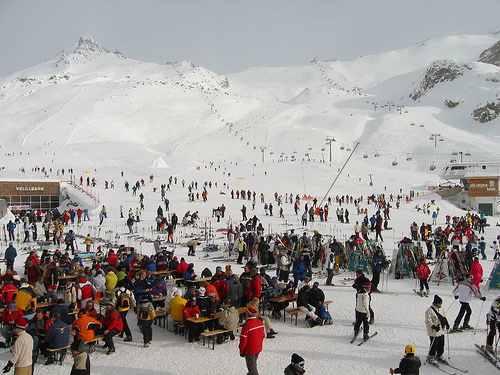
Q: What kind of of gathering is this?
A: A skier's event.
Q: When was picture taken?
A: In the winter.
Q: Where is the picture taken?
A: At a ski resort.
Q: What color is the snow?
A: White.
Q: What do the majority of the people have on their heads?
A: Hats.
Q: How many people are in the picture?
A: Over one hundred.